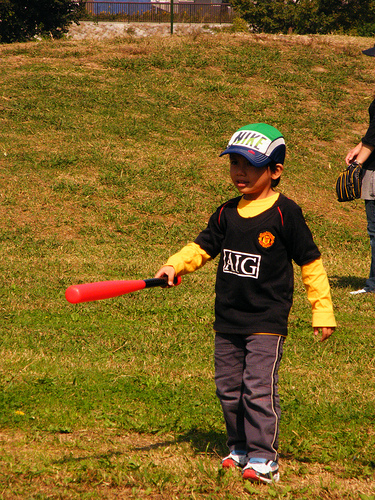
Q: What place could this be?
A: It is a lawn.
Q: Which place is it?
A: It is a lawn.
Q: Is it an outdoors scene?
A: Yes, it is outdoors.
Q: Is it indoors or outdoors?
A: It is outdoors.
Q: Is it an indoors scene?
A: No, it is outdoors.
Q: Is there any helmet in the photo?
A: No, there are no helmets.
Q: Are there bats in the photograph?
A: Yes, there is a bat.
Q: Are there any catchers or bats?
A: Yes, there is a bat.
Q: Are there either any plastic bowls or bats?
A: Yes, there is a plastic bat.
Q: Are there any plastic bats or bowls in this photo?
A: Yes, there is a plastic bat.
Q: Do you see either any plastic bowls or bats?
A: Yes, there is a plastic bat.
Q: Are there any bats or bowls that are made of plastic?
A: Yes, the bat is made of plastic.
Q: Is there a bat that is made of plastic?
A: Yes, there is a bat that is made of plastic.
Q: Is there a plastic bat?
A: Yes, there is a bat that is made of plastic.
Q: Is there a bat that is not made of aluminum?
A: Yes, there is a bat that is made of plastic.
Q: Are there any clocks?
A: No, there are no clocks.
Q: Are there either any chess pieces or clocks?
A: No, there are no clocks or chess pieces.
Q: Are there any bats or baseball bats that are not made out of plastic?
A: No, there is a bat but it is made of plastic.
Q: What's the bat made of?
A: The bat is made of plastic.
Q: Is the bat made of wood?
A: No, the bat is made of plastic.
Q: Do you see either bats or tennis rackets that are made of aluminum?
A: No, there is a bat but it is made of plastic.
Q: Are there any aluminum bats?
A: No, there is a bat but it is made of plastic.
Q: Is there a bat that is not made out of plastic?
A: No, there is a bat but it is made of plastic.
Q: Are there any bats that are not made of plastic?
A: No, there is a bat but it is made of plastic.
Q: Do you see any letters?
A: Yes, there are letters.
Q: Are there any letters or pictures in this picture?
A: Yes, there are letters.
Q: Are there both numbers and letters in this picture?
A: No, there are letters but no numbers.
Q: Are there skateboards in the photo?
A: No, there are no skateboards.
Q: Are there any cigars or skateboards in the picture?
A: No, there are no skateboards or cigars.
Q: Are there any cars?
A: No, there are no cars.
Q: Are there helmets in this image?
A: No, there are no helmets.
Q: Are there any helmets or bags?
A: No, there are no helmets or bags.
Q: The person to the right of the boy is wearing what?
A: The person is wearing a jacket.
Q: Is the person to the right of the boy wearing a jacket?
A: Yes, the person is wearing a jacket.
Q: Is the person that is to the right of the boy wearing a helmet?
A: No, the person is wearing a jacket.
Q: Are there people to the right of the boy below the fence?
A: Yes, there is a person to the right of the boy.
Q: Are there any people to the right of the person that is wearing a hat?
A: Yes, there is a person to the right of the boy.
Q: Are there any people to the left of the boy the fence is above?
A: No, the person is to the right of the boy.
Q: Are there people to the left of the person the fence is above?
A: No, the person is to the right of the boy.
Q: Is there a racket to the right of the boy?
A: No, there is a person to the right of the boy.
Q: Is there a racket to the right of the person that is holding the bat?
A: No, there is a person to the right of the boy.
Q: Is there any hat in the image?
A: Yes, there is a hat.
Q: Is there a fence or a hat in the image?
A: Yes, there is a hat.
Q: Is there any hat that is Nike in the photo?
A: Yes, there is a Nike hat.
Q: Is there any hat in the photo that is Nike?
A: Yes, there is a hat that is nike.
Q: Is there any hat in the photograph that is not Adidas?
A: Yes, there is an Nike hat.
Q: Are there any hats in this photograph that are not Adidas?
A: Yes, there is an Nike hat.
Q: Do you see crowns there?
A: No, there are no crowns.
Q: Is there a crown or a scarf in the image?
A: No, there are no crowns or scarves.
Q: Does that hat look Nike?
A: Yes, the hat is nike.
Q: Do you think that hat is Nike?
A: Yes, the hat is nike.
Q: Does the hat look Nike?
A: Yes, the hat is nike.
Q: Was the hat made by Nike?
A: Yes, the hat was made by nike.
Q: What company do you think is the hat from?
A: The hat is from nike.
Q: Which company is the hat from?
A: The hat is from nike.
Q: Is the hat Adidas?
A: No, the hat is nike.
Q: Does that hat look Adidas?
A: No, the hat is nike.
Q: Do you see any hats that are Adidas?
A: No, there is a hat but it is nike.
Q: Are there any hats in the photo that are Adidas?
A: No, there is a hat but it is nike.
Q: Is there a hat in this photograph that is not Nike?
A: No, there is a hat but it is nike.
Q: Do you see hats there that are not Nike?
A: No, there is a hat but it is nike.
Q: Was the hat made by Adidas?
A: No, the hat was made by nike.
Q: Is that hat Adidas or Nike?
A: The hat is nike.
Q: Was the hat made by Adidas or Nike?
A: The hat was made nike.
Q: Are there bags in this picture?
A: No, there are no bags.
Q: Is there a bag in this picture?
A: No, there are no bags.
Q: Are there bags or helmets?
A: No, there are no bags or helmets.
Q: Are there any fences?
A: Yes, there is a fence.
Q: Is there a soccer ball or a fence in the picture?
A: Yes, there is a fence.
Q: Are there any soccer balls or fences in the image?
A: Yes, there is a fence.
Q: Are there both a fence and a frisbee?
A: No, there is a fence but no frisbees.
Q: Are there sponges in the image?
A: No, there are no sponges.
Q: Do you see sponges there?
A: No, there are no sponges.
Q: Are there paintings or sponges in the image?
A: No, there are no sponges or paintings.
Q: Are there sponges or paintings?
A: No, there are no sponges or paintings.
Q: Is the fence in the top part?
A: Yes, the fence is in the top of the image.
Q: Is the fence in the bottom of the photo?
A: No, the fence is in the top of the image.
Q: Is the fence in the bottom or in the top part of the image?
A: The fence is in the top of the image.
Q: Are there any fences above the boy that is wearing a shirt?
A: Yes, there is a fence above the boy.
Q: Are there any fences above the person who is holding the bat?
A: Yes, there is a fence above the boy.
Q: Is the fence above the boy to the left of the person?
A: Yes, the fence is above the boy.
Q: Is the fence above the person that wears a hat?
A: Yes, the fence is above the boy.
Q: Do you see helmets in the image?
A: No, there are no helmets.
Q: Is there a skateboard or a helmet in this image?
A: No, there are no helmets or skateboards.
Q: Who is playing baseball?
A: The boy is playing baseball.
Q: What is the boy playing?
A: The boy is playing baseball.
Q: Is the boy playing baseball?
A: Yes, the boy is playing baseball.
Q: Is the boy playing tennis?
A: No, the boy is playing baseball.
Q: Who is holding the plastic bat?
A: The boy is holding the bat.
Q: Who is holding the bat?
A: The boy is holding the bat.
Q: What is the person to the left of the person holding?
A: The boy is holding the bat.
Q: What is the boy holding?
A: The boy is holding the bat.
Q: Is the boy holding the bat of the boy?
A: Yes, the boy is holding the bat.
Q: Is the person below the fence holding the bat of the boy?
A: Yes, the boy is holding the bat.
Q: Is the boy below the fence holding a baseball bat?
A: No, the boy is holding the bat.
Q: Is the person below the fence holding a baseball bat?
A: No, the boy is holding the bat.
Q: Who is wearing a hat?
A: The boy is wearing a hat.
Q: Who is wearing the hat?
A: The boy is wearing a hat.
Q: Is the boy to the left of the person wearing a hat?
A: Yes, the boy is wearing a hat.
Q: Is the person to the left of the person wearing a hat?
A: Yes, the boy is wearing a hat.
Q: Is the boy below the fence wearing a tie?
A: No, the boy is wearing a hat.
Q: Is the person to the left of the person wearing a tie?
A: No, the boy is wearing a hat.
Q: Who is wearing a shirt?
A: The boy is wearing a shirt.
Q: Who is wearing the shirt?
A: The boy is wearing a shirt.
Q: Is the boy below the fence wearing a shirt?
A: Yes, the boy is wearing a shirt.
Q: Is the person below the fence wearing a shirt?
A: Yes, the boy is wearing a shirt.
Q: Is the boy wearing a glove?
A: No, the boy is wearing a shirt.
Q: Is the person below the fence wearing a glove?
A: No, the boy is wearing a shirt.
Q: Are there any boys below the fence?
A: Yes, there is a boy below the fence.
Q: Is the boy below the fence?
A: Yes, the boy is below the fence.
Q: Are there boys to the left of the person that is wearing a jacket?
A: Yes, there is a boy to the left of the person.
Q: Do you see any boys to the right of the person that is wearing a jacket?
A: No, the boy is to the left of the person.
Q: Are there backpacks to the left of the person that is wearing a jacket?
A: No, there is a boy to the left of the person.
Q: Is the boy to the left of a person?
A: Yes, the boy is to the left of a person.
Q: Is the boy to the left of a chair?
A: No, the boy is to the left of a person.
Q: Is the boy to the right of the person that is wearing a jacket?
A: No, the boy is to the left of the person.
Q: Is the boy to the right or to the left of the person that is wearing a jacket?
A: The boy is to the left of the person.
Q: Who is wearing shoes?
A: The boy is wearing shoes.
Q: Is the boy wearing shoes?
A: Yes, the boy is wearing shoes.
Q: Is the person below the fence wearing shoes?
A: Yes, the boy is wearing shoes.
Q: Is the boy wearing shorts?
A: No, the boy is wearing shoes.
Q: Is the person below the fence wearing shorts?
A: No, the boy is wearing shoes.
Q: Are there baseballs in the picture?
A: Yes, there is a baseball.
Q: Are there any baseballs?
A: Yes, there is a baseball.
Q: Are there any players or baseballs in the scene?
A: Yes, there is a baseball.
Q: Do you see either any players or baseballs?
A: Yes, there is a baseball.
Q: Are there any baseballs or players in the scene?
A: Yes, there is a baseball.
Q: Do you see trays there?
A: No, there are no trays.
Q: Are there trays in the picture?
A: No, there are no trays.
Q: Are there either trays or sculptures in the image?
A: No, there are no trays or sculptures.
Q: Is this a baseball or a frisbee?
A: This is a baseball.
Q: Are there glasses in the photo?
A: No, there are no glasses.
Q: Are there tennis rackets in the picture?
A: No, there are no tennis rackets.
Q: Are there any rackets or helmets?
A: No, there are no rackets or helmets.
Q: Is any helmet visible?
A: No, there are no helmets.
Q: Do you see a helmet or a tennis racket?
A: No, there are no helmets or rackets.